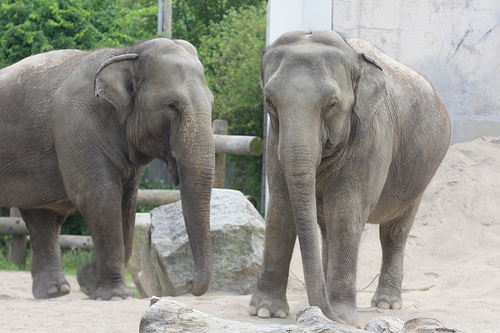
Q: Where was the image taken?
A: It was taken at the zoo.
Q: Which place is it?
A: It is a zoo.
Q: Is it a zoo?
A: Yes, it is a zoo.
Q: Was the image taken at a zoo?
A: Yes, it was taken in a zoo.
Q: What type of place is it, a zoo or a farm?
A: It is a zoo.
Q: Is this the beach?
A: No, it is the zoo.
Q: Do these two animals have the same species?
A: Yes, all the animals are elephants.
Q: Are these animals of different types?
A: No, all the animals are elephants.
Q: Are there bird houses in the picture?
A: No, there are no bird houses.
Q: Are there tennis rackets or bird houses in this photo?
A: No, there are no bird houses or tennis rackets.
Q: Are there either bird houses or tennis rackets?
A: No, there are no bird houses or tennis rackets.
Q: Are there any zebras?
A: No, there are no zebras.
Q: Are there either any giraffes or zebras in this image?
A: No, there are no zebras or giraffes.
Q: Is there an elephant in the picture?
A: Yes, there is an elephant.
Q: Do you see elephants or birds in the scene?
A: Yes, there is an elephant.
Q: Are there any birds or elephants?
A: Yes, there is an elephant.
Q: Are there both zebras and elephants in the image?
A: No, there is an elephant but no zebras.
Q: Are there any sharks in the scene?
A: No, there are no sharks.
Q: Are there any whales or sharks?
A: No, there are no sharks or whales.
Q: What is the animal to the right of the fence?
A: The animal is an elephant.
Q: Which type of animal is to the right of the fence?
A: The animal is an elephant.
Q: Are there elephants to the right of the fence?
A: Yes, there is an elephant to the right of the fence.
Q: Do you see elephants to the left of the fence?
A: No, the elephant is to the right of the fence.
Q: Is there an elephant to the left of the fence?
A: No, the elephant is to the right of the fence.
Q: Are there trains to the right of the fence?
A: No, there is an elephant to the right of the fence.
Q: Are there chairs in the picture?
A: No, there are no chairs.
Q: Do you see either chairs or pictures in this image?
A: No, there are no chairs or pictures.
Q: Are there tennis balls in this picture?
A: No, there are no tennis balls.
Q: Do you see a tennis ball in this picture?
A: No, there are no tennis balls.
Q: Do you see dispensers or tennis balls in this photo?
A: No, there are no tennis balls or dispensers.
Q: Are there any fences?
A: Yes, there is a fence.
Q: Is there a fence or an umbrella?
A: Yes, there is a fence.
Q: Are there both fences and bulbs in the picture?
A: No, there is a fence but no light bulbs.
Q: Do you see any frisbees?
A: No, there are no frisbees.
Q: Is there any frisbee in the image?
A: No, there are no frisbees.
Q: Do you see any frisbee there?
A: No, there are no frisbees.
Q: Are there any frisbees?
A: No, there are no frisbees.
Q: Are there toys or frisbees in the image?
A: No, there are no frisbees or toys.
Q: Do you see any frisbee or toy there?
A: No, there are no frisbees or toys.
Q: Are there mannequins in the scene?
A: No, there are no mannequins.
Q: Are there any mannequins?
A: No, there are no mannequins.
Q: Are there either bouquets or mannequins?
A: No, there are no mannequins or bouquets.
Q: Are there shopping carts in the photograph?
A: No, there are no shopping carts.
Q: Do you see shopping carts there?
A: No, there are no shopping carts.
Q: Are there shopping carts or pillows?
A: No, there are no shopping carts or pillows.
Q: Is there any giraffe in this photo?
A: No, there are no giraffes.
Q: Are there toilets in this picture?
A: No, there are no toilets.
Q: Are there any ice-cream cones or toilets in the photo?
A: No, there are no toilets or ice-cream cones.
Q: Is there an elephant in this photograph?
A: Yes, there is an elephant.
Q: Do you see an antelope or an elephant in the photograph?
A: Yes, there is an elephant.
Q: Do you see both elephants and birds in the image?
A: No, there is an elephant but no birds.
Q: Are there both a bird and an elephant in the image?
A: No, there is an elephant but no birds.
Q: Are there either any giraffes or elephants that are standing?
A: Yes, the elephant is standing.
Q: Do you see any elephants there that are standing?
A: Yes, there is an elephant that is standing.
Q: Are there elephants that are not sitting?
A: Yes, there is an elephant that is standing.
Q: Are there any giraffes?
A: No, there are no giraffes.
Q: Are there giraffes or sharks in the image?
A: No, there are no giraffes or sharks.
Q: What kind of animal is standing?
A: The animal is an elephant.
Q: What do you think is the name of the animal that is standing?
A: The animal is an elephant.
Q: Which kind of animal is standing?
A: The animal is an elephant.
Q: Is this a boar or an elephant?
A: This is an elephant.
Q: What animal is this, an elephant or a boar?
A: This is an elephant.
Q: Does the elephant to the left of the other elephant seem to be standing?
A: Yes, the elephant is standing.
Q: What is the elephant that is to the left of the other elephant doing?
A: The elephant is standing.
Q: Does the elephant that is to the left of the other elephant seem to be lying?
A: No, the elephant is standing.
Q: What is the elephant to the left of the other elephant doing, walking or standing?
A: The elephant is standing.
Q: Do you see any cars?
A: No, there are no cars.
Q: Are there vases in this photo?
A: No, there are no vases.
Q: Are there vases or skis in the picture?
A: No, there are no vases or skis.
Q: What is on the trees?
A: The leaves are on the trees.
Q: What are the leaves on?
A: The leaves are on the trees.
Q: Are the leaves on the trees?
A: Yes, the leaves are on the trees.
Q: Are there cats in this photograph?
A: No, there are no cats.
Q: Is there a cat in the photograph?
A: No, there are no cats.